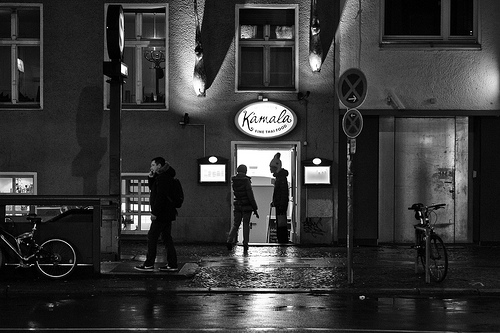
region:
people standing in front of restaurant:
[116, 5, 342, 281]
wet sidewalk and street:
[25, 240, 482, 325]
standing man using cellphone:
[135, 136, 185, 271]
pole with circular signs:
[331, 60, 366, 280]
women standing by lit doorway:
[227, 140, 304, 252]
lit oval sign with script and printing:
[232, 92, 297, 139]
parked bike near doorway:
[371, 110, 471, 290]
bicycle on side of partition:
[0, 190, 86, 282]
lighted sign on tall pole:
[100, 1, 130, 211]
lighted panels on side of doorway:
[195, 150, 336, 185]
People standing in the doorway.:
[221, 145, 301, 277]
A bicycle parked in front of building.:
[405, 193, 460, 285]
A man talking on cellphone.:
[125, 152, 189, 259]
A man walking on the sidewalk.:
[127, 155, 204, 272]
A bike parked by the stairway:
[11, 205, 95, 280]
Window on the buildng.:
[219, 5, 314, 103]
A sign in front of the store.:
[224, 100, 300, 141]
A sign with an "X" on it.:
[319, 69, 373, 143]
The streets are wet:
[45, 276, 453, 322]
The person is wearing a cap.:
[262, 148, 292, 166]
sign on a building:
[225, 98, 301, 138]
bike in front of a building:
[403, 201, 451, 286]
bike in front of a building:
[0, 212, 85, 285]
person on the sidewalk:
[130, 155, 186, 277]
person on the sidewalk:
[220, 165, 261, 257]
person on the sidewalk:
[265, 149, 297, 253]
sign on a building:
[195, 153, 234, 190]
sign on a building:
[298, 153, 336, 189]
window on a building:
[102, 0, 174, 112]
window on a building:
[1, 0, 44, 110]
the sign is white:
[208, 90, 301, 147]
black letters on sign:
[230, 106, 284, 130]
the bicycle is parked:
[399, 192, 483, 308]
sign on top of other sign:
[325, 58, 387, 150]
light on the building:
[193, 73, 225, 114]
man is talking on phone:
[130, 145, 202, 216]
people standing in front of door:
[224, 151, 332, 267]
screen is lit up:
[296, 154, 355, 256]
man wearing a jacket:
[138, 165, 193, 230]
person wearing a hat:
[260, 148, 291, 179]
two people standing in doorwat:
[226, 144, 293, 233]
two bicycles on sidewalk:
[5, 195, 447, 287]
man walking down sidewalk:
[129, 156, 194, 275]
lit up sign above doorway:
[231, 96, 301, 139]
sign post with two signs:
[334, 60, 369, 263]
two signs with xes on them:
[330, 65, 377, 142]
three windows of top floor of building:
[2, 3, 314, 114]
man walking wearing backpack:
[138, 145, 198, 276]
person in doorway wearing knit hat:
[266, 148, 304, 250]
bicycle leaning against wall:
[5, 205, 87, 281]